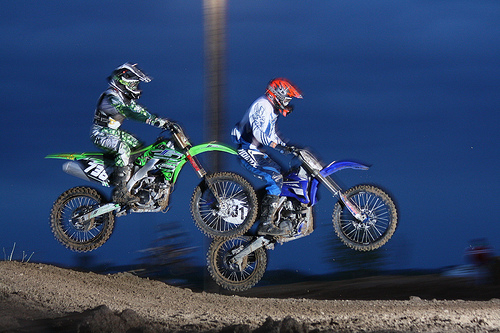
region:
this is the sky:
[305, 16, 447, 117]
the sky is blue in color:
[362, 27, 459, 121]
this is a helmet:
[272, 80, 294, 102]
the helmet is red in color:
[271, 78, 290, 84]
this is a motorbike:
[301, 154, 393, 247]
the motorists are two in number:
[88, 59, 310, 164]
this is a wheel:
[353, 183, 396, 250]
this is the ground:
[71, 272, 164, 326]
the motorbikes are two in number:
[94, 163, 358, 281]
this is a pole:
[203, 5, 226, 108]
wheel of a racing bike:
[340, 186, 395, 253]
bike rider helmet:
[259, 72, 309, 126]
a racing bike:
[42, 149, 251, 241]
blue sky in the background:
[327, 13, 468, 154]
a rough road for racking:
[26, 265, 438, 328]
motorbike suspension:
[317, 173, 374, 226]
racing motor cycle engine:
[265, 187, 322, 247]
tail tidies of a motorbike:
[31, 140, 102, 166]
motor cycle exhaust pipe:
[41, 161, 92, 181]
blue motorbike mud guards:
[321, 164, 387, 176]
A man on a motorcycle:
[212, 68, 406, 298]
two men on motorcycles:
[50, 57, 417, 314]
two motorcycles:
[41, 128, 432, 310]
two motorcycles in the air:
[23, 125, 428, 279]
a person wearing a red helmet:
[233, 60, 334, 140]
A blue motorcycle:
[229, 151, 421, 269]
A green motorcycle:
[11, 128, 270, 254]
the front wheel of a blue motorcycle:
[313, 151, 417, 282]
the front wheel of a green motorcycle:
[176, 134, 256, 254]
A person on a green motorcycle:
[45, 44, 192, 282]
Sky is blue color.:
[340, 26, 489, 155]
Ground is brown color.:
[9, 267, 146, 306]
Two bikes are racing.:
[44, 56, 406, 288]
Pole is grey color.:
[194, 6, 238, 273]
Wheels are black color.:
[52, 181, 413, 294]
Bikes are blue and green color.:
[40, 116, 391, 273]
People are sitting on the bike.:
[99, 61, 333, 210]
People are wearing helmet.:
[88, 56, 313, 118]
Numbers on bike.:
[79, 155, 266, 230]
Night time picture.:
[32, 35, 467, 306]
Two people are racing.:
[58, 58, 401, 290]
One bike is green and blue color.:
[44, 67, 396, 286]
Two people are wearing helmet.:
[110, 55, 299, 125]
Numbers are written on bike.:
[56, 143, 276, 233]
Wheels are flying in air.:
[36, 126, 423, 277]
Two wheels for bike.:
[45, 146, 253, 249]